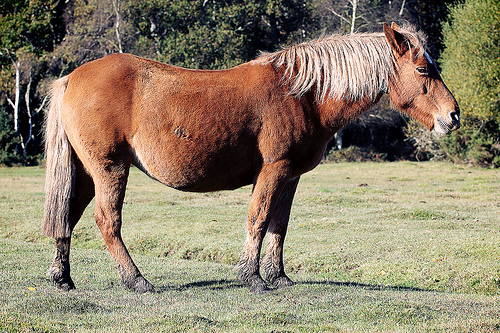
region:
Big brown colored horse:
[39, 18, 477, 295]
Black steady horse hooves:
[233, 258, 297, 295]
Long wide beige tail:
[38, 76, 76, 243]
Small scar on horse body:
[166, 118, 203, 149]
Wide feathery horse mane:
[265, 28, 385, 99]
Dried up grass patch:
[304, 286, 414, 323]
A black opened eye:
[411, 58, 428, 78]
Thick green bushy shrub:
[145, 4, 261, 52]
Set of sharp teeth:
[432, 112, 454, 134]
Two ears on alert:
[376, 18, 404, 45]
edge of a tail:
[109, 236, 129, 256]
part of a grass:
[359, 102, 368, 117]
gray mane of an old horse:
[253, 20, 414, 105]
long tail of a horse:
[32, 72, 73, 244]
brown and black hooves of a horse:
[32, 250, 289, 293]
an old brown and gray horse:
[36, 13, 466, 299]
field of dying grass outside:
[2, 161, 498, 328]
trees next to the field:
[2, 2, 499, 160]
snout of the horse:
[432, 100, 466, 136]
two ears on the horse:
[381, 17, 405, 52]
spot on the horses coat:
[170, 121, 196, 144]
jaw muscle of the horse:
[391, 89, 413, 113]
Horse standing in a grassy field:
[26, 27, 471, 302]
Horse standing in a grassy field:
[19, 35, 405, 300]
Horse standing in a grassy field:
[28, 20, 465, 301]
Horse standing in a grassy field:
[21, 23, 467, 299]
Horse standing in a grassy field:
[13, 29, 466, 301]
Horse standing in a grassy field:
[16, 18, 471, 300]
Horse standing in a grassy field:
[25, 28, 461, 298]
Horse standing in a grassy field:
[26, 13, 471, 302]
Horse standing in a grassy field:
[18, 17, 472, 304]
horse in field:
[21, 15, 469, 307]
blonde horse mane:
[240, 18, 429, 104]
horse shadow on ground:
[170, 256, 451, 315]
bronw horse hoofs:
[35, 264, 162, 305]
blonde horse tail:
[27, 68, 85, 244]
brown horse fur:
[200, 95, 262, 117]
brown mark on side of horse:
[167, 118, 198, 145]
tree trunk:
[1, 61, 39, 153]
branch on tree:
[322, 4, 351, 26]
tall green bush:
[428, 0, 498, 167]